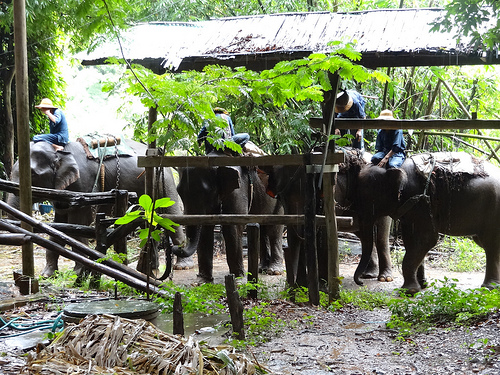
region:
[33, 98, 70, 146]
person sitting on an elephant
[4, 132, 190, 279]
large gray elephant under person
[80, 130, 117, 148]
package on elephant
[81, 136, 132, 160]
blanket under package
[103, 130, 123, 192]
metal chain on elephant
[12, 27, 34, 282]
wooden pole in front of elephant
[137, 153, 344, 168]
wooden railing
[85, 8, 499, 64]
thatch roof over elephants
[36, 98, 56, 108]
person wearing a straw hat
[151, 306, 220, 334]
puddle on the ground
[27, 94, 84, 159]
a man in a straw hat on an elephant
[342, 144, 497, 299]
an elephant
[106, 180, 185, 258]
green leaves on a plant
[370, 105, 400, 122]
a straw hat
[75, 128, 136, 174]
some supplies strapped to an elephant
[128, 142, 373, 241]
some wooden fencing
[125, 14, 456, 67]
a thatched roof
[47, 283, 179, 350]
a lid over a sewer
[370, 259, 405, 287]
the foot of an elephant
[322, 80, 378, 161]
a man standing on an elephant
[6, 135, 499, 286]
Four grey elephants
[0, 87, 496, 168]
Four people in blue outfits with straw hats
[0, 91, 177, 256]
Person sitting on the neck of an elephant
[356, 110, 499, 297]
Elephant with a person on its back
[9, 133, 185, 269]
Elephant with a pack chained to its back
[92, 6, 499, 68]
Thatch roof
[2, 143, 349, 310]
Wooden posts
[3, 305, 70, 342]
Green hose sitting on the ground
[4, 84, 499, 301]
Elephants and people preparing for a ride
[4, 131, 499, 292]
Elephants in a line with the smallest on the right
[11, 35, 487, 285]
A heard of elephants.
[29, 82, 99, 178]
People are on top of the elephants.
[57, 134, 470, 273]
The elephants are next to a fence.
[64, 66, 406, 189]
Picture taken outdoors.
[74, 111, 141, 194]
Packs are tied to the elephants.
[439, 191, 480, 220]
The elephant is brown.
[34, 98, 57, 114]
A person wears a hat.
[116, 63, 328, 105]
The bush is full of leaves.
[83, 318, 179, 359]
Dead straw on the ground.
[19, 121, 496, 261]
Five elephants standing.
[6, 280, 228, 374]
a brown haystack on the ground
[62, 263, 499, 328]
green weeds on the ground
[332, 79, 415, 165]
two farm workers by the elephants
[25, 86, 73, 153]
man riding an elephant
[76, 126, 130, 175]
saddle on the back of an elephant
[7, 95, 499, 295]
elephants in a pen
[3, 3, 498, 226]
tops of green plants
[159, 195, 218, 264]
elephant trunk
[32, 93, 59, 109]
tan straw hat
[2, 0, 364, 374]
wooden poles around the pen